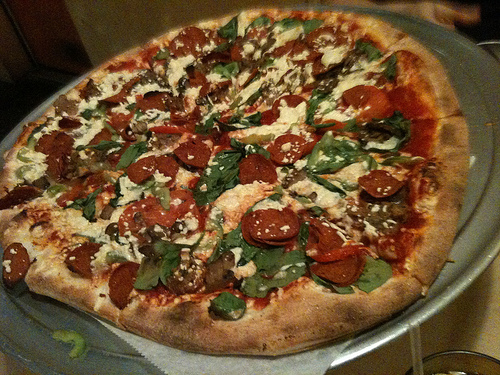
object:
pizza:
[0, 3, 475, 363]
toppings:
[312, 174, 349, 201]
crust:
[120, 47, 146, 68]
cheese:
[278, 107, 302, 124]